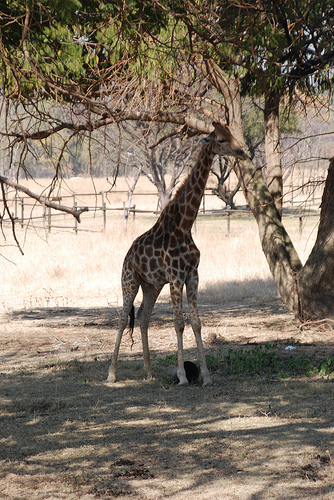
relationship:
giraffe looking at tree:
[106, 118, 252, 390] [1, 0, 333, 325]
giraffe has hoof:
[106, 118, 252, 390] [176, 374, 193, 386]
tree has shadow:
[1, 0, 333, 325] [1, 274, 294, 333]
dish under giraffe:
[177, 360, 200, 385] [106, 118, 252, 390]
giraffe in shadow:
[106, 118, 252, 390] [1, 274, 294, 333]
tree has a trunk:
[1, 0, 333, 325] [233, 146, 331, 327]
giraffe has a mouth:
[106, 118, 252, 390] [230, 153, 251, 161]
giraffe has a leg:
[106, 118, 252, 390] [102, 274, 144, 385]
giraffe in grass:
[106, 118, 252, 390] [151, 337, 332, 381]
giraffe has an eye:
[106, 118, 252, 390] [219, 135, 228, 145]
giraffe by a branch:
[106, 118, 252, 390] [2, 107, 221, 158]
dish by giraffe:
[177, 360, 200, 385] [106, 118, 252, 390]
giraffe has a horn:
[106, 118, 252, 390] [221, 119, 232, 130]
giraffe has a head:
[106, 118, 252, 390] [207, 120, 249, 164]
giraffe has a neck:
[106, 118, 252, 390] [152, 146, 216, 231]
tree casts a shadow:
[1, 0, 333, 325] [1, 274, 294, 333]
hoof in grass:
[176, 374, 193, 386] [151, 337, 332, 381]